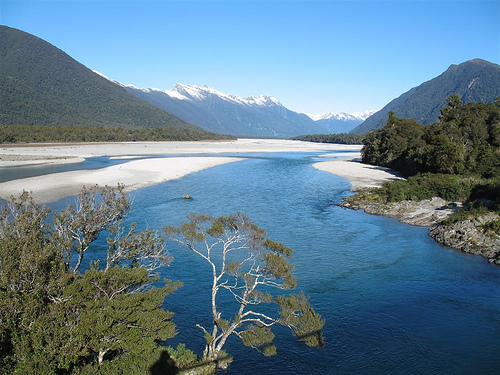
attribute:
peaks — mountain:
[117, 73, 374, 131]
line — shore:
[314, 145, 495, 268]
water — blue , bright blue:
[0, 149, 496, 372]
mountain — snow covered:
[108, 81, 378, 140]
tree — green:
[430, 88, 471, 152]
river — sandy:
[49, 150, 495, 372]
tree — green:
[468, 103, 491, 173]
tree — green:
[486, 105, 498, 141]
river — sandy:
[6, 139, 489, 367]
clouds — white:
[97, 22, 154, 62]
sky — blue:
[3, 5, 499, 137]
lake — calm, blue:
[8, 143, 498, 372]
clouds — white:
[308, 40, 367, 85]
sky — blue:
[0, 3, 499, 112]